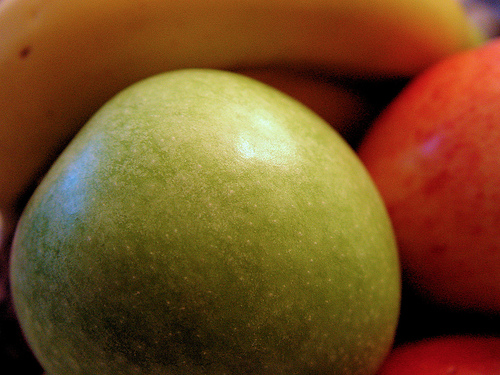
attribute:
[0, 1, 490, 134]
banana — long, yellow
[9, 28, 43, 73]
spot — brown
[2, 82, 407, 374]
apple — shiny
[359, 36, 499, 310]
apple — red, shiny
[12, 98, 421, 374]
apple — green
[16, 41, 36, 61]
brown spot — small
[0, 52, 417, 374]
apple — green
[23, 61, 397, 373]
apple — clean, full, round, yellow specked, dark underside, fresh , green 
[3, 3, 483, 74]
banana — yellow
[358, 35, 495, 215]
apple — red 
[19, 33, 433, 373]
apple — big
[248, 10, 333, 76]
banana — yellow, fresh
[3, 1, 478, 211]
banana — yellow